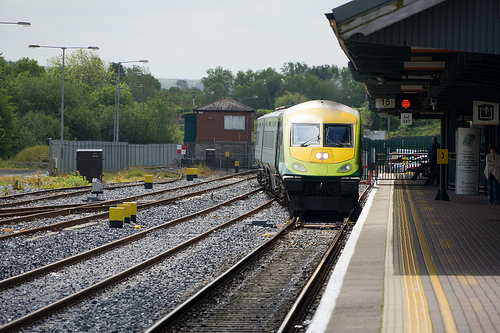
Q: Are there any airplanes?
A: No, there are no airplanes.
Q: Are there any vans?
A: No, there are no vans.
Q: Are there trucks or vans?
A: No, there are no vans or trucks.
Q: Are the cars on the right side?
A: Yes, the cars are on the right of the image.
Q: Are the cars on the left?
A: No, the cars are on the right of the image.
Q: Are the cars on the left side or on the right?
A: The cars are on the right of the image.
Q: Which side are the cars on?
A: The cars are on the right of the image.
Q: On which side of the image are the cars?
A: The cars are on the right of the image.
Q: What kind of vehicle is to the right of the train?
A: The vehicles are cars.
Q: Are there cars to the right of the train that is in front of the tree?
A: Yes, there are cars to the right of the train.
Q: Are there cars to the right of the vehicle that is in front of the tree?
A: Yes, there are cars to the right of the train.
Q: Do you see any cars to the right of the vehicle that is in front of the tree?
A: Yes, there are cars to the right of the train.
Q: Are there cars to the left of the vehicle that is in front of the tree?
A: No, the cars are to the right of the train.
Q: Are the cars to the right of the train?
A: Yes, the cars are to the right of the train.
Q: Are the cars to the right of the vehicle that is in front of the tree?
A: Yes, the cars are to the right of the train.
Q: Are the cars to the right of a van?
A: No, the cars are to the right of the train.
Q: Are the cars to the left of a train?
A: No, the cars are to the right of a train.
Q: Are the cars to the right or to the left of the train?
A: The cars are to the right of the train.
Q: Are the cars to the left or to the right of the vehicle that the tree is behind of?
A: The cars are to the right of the train.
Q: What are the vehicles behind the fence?
A: The vehicles are cars.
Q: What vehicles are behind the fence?
A: The vehicles are cars.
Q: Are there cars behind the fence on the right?
A: Yes, there are cars behind the fence.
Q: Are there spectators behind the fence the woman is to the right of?
A: No, there are cars behind the fence.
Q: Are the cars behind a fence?
A: Yes, the cars are behind a fence.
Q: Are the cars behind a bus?
A: No, the cars are behind a fence.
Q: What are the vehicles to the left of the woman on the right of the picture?
A: The vehicles are cars.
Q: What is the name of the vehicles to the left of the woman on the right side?
A: The vehicles are cars.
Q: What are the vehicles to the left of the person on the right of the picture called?
A: The vehicles are cars.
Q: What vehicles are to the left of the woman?
A: The vehicles are cars.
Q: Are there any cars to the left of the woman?
A: Yes, there are cars to the left of the woman.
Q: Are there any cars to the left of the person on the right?
A: Yes, there are cars to the left of the woman.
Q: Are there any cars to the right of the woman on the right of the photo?
A: No, the cars are to the left of the woman.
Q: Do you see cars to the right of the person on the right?
A: No, the cars are to the left of the woman.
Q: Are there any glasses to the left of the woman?
A: No, there are cars to the left of the woman.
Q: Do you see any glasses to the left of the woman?
A: No, there are cars to the left of the woman.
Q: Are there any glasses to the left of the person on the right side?
A: No, there are cars to the left of the woman.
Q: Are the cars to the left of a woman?
A: Yes, the cars are to the left of a woman.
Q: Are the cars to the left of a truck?
A: No, the cars are to the left of a woman.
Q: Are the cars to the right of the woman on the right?
A: No, the cars are to the left of the woman.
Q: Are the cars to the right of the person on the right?
A: No, the cars are to the left of the woman.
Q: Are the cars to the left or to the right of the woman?
A: The cars are to the left of the woman.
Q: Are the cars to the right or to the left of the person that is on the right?
A: The cars are to the left of the woman.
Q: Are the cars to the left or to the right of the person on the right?
A: The cars are to the left of the woman.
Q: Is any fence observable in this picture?
A: Yes, there is a fence.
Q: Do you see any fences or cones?
A: Yes, there is a fence.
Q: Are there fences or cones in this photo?
A: Yes, there is a fence.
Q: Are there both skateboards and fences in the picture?
A: No, there is a fence but no skateboards.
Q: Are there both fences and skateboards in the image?
A: No, there is a fence but no skateboards.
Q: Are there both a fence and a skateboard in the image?
A: No, there is a fence but no skateboards.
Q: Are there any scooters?
A: No, there are no scooters.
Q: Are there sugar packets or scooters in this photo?
A: No, there are no scooters or sugar packets.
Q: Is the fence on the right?
A: Yes, the fence is on the right of the image.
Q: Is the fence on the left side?
A: No, the fence is on the right of the image.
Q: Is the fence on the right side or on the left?
A: The fence is on the right of the image.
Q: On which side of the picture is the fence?
A: The fence is on the right of the image.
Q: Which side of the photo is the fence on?
A: The fence is on the right of the image.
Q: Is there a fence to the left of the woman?
A: Yes, there is a fence to the left of the woman.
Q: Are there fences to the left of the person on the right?
A: Yes, there is a fence to the left of the woman.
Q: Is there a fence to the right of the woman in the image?
A: No, the fence is to the left of the woman.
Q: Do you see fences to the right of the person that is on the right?
A: No, the fence is to the left of the woman.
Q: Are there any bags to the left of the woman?
A: No, there is a fence to the left of the woman.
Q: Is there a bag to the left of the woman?
A: No, there is a fence to the left of the woman.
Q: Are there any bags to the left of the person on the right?
A: No, there is a fence to the left of the woman.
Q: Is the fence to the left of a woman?
A: Yes, the fence is to the left of a woman.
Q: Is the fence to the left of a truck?
A: No, the fence is to the left of a woman.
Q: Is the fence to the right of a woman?
A: No, the fence is to the left of a woman.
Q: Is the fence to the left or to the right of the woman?
A: The fence is to the left of the woman.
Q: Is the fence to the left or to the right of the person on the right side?
A: The fence is to the left of the woman.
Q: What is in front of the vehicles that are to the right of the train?
A: The fence is in front of the cars.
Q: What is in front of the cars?
A: The fence is in front of the cars.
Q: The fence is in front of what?
A: The fence is in front of the cars.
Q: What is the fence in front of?
A: The fence is in front of the cars.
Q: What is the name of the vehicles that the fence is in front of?
A: The vehicles are cars.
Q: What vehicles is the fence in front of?
A: The fence is in front of the cars.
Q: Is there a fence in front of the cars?
A: Yes, there is a fence in front of the cars.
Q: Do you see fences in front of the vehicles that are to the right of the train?
A: Yes, there is a fence in front of the cars.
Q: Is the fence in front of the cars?
A: Yes, the fence is in front of the cars.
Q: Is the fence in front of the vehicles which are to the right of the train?
A: Yes, the fence is in front of the cars.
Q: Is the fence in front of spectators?
A: No, the fence is in front of the cars.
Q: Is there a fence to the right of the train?
A: Yes, there is a fence to the right of the train.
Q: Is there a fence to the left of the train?
A: No, the fence is to the right of the train.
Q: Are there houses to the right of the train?
A: No, there is a fence to the right of the train.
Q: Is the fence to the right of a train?
A: Yes, the fence is to the right of a train.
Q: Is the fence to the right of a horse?
A: No, the fence is to the right of a train.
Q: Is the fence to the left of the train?
A: No, the fence is to the right of the train.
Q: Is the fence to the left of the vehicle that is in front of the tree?
A: No, the fence is to the right of the train.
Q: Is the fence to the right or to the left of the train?
A: The fence is to the right of the train.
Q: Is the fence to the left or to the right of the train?
A: The fence is to the right of the train.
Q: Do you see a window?
A: Yes, there is a window.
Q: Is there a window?
A: Yes, there is a window.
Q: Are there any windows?
A: Yes, there is a window.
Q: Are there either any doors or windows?
A: Yes, there is a window.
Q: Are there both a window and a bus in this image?
A: No, there is a window but no buses.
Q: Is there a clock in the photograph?
A: No, there are no clocks.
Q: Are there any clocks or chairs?
A: No, there are no clocks or chairs.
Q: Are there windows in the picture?
A: Yes, there is a window.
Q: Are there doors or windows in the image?
A: Yes, there is a window.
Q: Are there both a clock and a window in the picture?
A: No, there is a window but no clocks.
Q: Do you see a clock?
A: No, there are no clocks.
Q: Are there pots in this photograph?
A: No, there are no pots.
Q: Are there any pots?
A: No, there are no pots.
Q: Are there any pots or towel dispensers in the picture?
A: No, there are no pots or towel dispensers.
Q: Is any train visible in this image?
A: Yes, there is a train.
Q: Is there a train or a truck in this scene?
A: Yes, there is a train.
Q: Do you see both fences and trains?
A: Yes, there are both a train and a fence.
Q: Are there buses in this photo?
A: No, there are no buses.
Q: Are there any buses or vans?
A: No, there are no buses or vans.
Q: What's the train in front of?
A: The train is in front of the tree.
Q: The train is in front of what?
A: The train is in front of the tree.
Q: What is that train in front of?
A: The train is in front of the tree.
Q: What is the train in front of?
A: The train is in front of the tree.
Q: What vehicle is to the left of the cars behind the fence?
A: The vehicle is a train.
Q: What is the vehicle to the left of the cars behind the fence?
A: The vehicle is a train.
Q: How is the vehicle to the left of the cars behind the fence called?
A: The vehicle is a train.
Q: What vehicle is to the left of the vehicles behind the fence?
A: The vehicle is a train.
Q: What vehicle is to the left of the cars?
A: The vehicle is a train.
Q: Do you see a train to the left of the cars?
A: Yes, there is a train to the left of the cars.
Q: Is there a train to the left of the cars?
A: Yes, there is a train to the left of the cars.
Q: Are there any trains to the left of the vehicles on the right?
A: Yes, there is a train to the left of the cars.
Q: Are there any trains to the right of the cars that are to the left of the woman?
A: No, the train is to the left of the cars.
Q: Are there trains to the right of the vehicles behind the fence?
A: No, the train is to the left of the cars.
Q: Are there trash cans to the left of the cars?
A: No, there is a train to the left of the cars.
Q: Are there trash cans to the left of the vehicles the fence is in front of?
A: No, there is a train to the left of the cars.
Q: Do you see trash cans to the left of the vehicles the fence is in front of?
A: No, there is a train to the left of the cars.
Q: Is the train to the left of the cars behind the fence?
A: Yes, the train is to the left of the cars.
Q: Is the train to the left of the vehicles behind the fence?
A: Yes, the train is to the left of the cars.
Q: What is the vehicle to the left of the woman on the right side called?
A: The vehicle is a train.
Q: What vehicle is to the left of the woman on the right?
A: The vehicle is a train.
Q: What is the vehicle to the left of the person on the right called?
A: The vehicle is a train.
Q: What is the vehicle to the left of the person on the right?
A: The vehicle is a train.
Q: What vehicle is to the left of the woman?
A: The vehicle is a train.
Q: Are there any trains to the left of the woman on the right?
A: Yes, there is a train to the left of the woman.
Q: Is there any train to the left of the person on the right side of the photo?
A: Yes, there is a train to the left of the woman.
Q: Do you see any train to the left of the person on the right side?
A: Yes, there is a train to the left of the woman.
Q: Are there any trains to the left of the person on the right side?
A: Yes, there is a train to the left of the woman.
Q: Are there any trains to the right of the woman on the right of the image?
A: No, the train is to the left of the woman.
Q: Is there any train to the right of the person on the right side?
A: No, the train is to the left of the woman.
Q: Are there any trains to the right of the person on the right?
A: No, the train is to the left of the woman.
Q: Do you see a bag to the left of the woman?
A: No, there is a train to the left of the woman.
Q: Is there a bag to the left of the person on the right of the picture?
A: No, there is a train to the left of the woman.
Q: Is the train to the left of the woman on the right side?
A: Yes, the train is to the left of the woman.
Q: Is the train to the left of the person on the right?
A: Yes, the train is to the left of the woman.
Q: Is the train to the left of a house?
A: No, the train is to the left of the woman.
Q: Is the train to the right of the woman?
A: No, the train is to the left of the woman.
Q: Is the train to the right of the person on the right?
A: No, the train is to the left of the woman.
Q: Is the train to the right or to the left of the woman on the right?
A: The train is to the left of the woman.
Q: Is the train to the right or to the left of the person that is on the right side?
A: The train is to the left of the woman.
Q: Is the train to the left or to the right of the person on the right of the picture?
A: The train is to the left of the woman.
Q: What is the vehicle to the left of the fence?
A: The vehicle is a train.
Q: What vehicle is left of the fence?
A: The vehicle is a train.